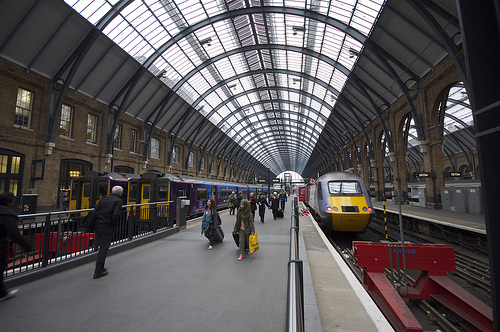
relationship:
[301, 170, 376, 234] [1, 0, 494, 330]
train in station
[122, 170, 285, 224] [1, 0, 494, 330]
train in station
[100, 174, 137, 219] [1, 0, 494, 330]
train in station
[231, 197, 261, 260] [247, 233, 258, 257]
woman carrying bag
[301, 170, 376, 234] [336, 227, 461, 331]
train on tracks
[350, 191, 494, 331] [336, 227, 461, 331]
barrier on tracks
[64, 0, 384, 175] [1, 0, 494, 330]
ceiling in station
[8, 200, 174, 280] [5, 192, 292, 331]
fence along platform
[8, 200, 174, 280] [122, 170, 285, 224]
fence along train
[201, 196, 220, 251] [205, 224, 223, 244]
woman pulling suitcase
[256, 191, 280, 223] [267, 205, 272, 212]
couple holding hands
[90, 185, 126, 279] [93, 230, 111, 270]
man wearing trousers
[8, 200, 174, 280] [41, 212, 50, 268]
fence has post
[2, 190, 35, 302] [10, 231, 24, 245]
man has elbow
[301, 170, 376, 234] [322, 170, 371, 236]
train has front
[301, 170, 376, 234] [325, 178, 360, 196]
train has window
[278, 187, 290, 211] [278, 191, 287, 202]
person wearing jacket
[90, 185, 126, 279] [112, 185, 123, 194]
man has hair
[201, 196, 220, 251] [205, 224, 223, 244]
woman pulls suitcase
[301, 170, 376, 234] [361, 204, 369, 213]
train has headlight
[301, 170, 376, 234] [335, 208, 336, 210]
train has headlight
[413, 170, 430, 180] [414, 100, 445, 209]
sign on pillar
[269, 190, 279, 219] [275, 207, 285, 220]
man with bag